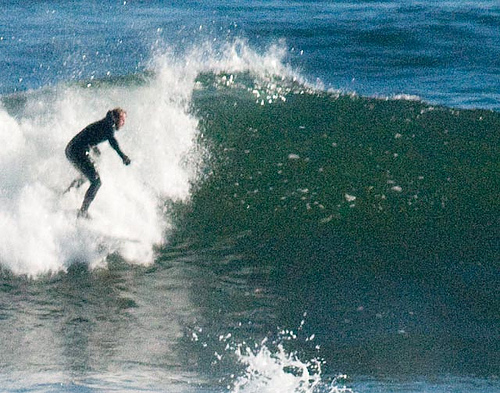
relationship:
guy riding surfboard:
[62, 107, 131, 220] [63, 206, 143, 246]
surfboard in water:
[71, 210, 141, 245] [0, 3, 497, 386]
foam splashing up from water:
[0, 27, 459, 393] [0, 3, 497, 386]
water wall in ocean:
[0, 92, 182, 247] [2, 1, 481, 388]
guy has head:
[62, 107, 131, 220] [105, 103, 129, 132]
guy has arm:
[62, 107, 131, 220] [106, 130, 125, 160]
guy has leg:
[62, 107, 131, 220] [66, 152, 104, 212]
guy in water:
[62, 107, 131, 220] [0, 3, 497, 386]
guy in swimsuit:
[62, 107, 131, 220] [62, 117, 128, 219]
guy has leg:
[62, 107, 131, 220] [64, 170, 88, 195]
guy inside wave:
[62, 107, 131, 220] [0, 54, 298, 284]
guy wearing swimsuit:
[62, 107, 131, 220] [62, 117, 128, 219]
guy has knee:
[62, 107, 131, 220] [88, 174, 103, 190]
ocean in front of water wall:
[0, 0, 500, 393] [0, 92, 182, 247]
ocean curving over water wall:
[0, 0, 500, 393] [0, 92, 182, 247]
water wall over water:
[0, 63, 499, 273] [0, 3, 497, 386]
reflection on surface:
[2, 250, 211, 392] [0, 0, 499, 388]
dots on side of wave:
[197, 94, 422, 222] [2, 65, 499, 285]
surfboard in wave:
[74, 225, 143, 243] [4, 39, 301, 278]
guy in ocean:
[62, 107, 131, 220] [2, 1, 481, 388]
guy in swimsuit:
[58, 102, 137, 221] [61, 119, 133, 219]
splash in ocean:
[188, 311, 349, 391] [2, 1, 481, 388]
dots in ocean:
[224, 76, 484, 222] [2, 1, 481, 388]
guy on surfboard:
[62, 107, 131, 220] [49, 195, 140, 247]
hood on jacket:
[102, 107, 117, 127] [72, 109, 137, 167]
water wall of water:
[0, 92, 182, 247] [0, 3, 497, 386]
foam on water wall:
[203, 106, 460, 234] [0, 92, 182, 247]